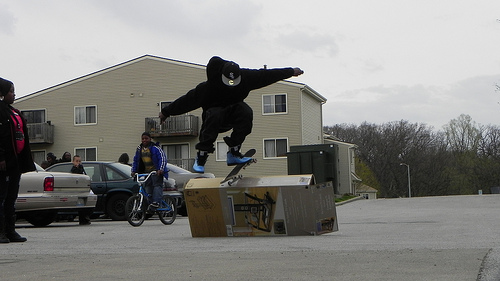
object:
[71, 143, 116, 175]
window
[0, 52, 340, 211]
building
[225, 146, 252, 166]
shoe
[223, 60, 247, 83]
hat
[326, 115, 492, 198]
leafless trees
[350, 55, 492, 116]
white cloth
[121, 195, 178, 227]
wheels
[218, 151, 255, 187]
skateboard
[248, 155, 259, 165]
wheel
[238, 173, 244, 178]
wheel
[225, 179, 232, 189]
wheel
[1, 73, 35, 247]
person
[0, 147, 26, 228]
pants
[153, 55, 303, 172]
skateboarder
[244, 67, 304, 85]
arm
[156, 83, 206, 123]
arm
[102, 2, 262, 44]
cloud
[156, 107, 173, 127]
hand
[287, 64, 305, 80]
hand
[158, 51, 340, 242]
thing clouds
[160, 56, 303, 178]
man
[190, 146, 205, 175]
shoe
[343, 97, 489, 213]
trees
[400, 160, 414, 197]
streetlight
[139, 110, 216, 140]
balcony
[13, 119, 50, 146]
balcony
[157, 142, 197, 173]
balcony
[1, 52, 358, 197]
house